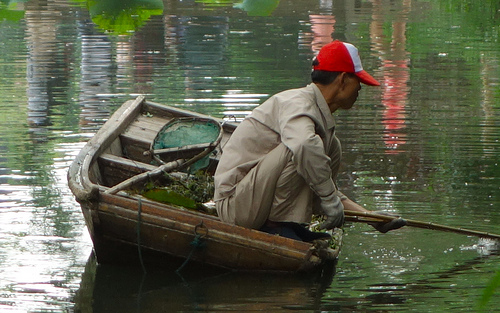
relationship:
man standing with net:
[214, 40, 406, 242] [349, 207, 500, 251]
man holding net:
[214, 40, 406, 242] [349, 207, 500, 251]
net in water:
[349, 207, 500, 251] [344, 135, 499, 311]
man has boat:
[214, 40, 406, 242] [66, 99, 346, 274]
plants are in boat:
[140, 172, 217, 214] [66, 99, 346, 274]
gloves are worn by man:
[317, 191, 407, 232] [214, 40, 406, 242]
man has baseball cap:
[214, 40, 406, 242] [311, 38, 383, 89]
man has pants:
[214, 40, 406, 242] [214, 132, 341, 229]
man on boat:
[214, 40, 406, 242] [66, 99, 346, 274]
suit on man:
[213, 88, 352, 233] [214, 40, 406, 242]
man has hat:
[214, 40, 406, 242] [311, 38, 383, 89]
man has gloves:
[214, 40, 406, 242] [317, 191, 407, 232]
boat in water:
[66, 99, 346, 274] [0, 1, 499, 313]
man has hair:
[214, 40, 406, 242] [311, 57, 355, 86]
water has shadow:
[0, 1, 499, 313] [0, 4, 499, 167]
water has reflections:
[0, 1, 499, 313] [0, 4, 499, 167]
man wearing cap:
[214, 40, 406, 242] [311, 38, 383, 89]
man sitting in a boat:
[214, 40, 406, 242] [66, 99, 346, 274]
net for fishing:
[349, 207, 500, 251] [152, 117, 223, 177]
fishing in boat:
[152, 117, 223, 177] [66, 99, 346, 274]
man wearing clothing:
[214, 40, 406, 242] [213, 88, 352, 233]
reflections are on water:
[0, 4, 499, 167] [0, 1, 499, 313]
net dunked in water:
[349, 207, 500, 251] [344, 135, 499, 311]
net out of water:
[152, 117, 223, 177] [0, 1, 499, 313]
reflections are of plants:
[367, 0, 500, 106] [3, 4, 499, 71]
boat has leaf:
[66, 99, 346, 274] [143, 184, 205, 210]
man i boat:
[214, 40, 406, 242] [66, 99, 346, 274]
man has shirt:
[214, 40, 406, 242] [211, 87, 341, 206]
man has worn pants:
[214, 40, 406, 242] [214, 132, 341, 229]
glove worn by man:
[318, 196, 346, 237] [214, 40, 406, 242]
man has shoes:
[214, 40, 406, 242] [264, 220, 331, 243]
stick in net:
[147, 143, 215, 157] [152, 117, 223, 177]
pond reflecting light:
[0, 1, 499, 313] [3, 56, 264, 310]